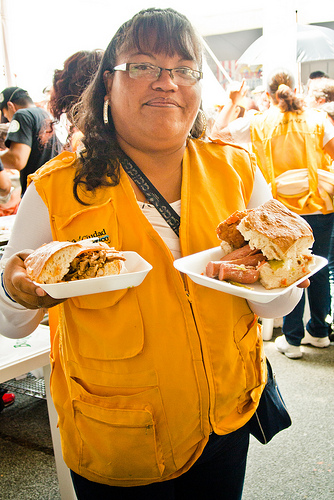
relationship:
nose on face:
[150, 70, 177, 91] [118, 38, 203, 157]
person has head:
[1, 1, 321, 498] [93, 9, 208, 155]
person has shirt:
[1, 1, 321, 498] [22, 133, 288, 492]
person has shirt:
[302, 73, 330, 130] [313, 104, 332, 120]